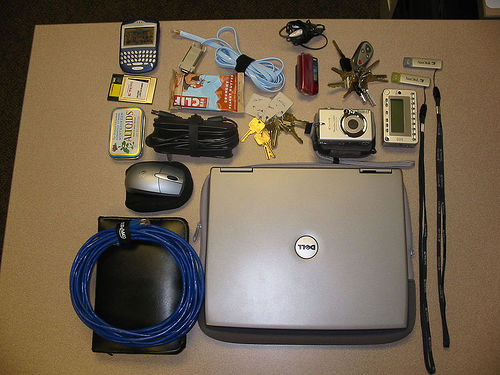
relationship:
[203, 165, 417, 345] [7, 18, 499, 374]
laptop on table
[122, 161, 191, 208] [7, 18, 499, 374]
mouse on table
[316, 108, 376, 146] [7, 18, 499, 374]
camera on table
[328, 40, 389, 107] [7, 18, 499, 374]
keys on table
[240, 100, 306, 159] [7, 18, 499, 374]
keys on table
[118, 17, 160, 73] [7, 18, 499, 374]
phone on table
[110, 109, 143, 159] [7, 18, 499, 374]
altoids on table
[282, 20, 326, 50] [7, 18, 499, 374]
earbuds on table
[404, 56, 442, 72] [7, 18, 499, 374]
storage-device on table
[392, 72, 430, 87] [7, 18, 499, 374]
storage-device on table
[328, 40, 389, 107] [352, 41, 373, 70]
keys with remote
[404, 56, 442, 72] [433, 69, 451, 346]
storage-device on lanyard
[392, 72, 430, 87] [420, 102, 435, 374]
storage-device on lanyard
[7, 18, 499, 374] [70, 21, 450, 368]
table covered in electronics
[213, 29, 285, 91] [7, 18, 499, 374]
wire-roll on table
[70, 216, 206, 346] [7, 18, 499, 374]
wire-roll on table